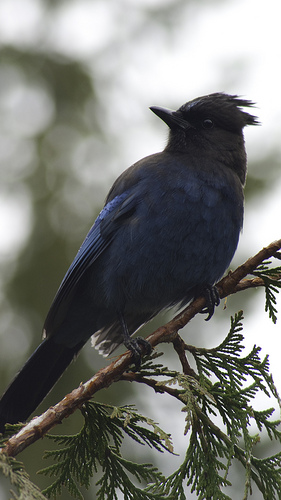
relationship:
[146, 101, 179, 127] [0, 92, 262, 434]
beak of bird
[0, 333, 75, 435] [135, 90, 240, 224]
tail of bird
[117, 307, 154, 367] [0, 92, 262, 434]
leg of bird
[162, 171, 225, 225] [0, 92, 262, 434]
feathers of bird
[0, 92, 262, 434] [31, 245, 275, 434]
bird on limb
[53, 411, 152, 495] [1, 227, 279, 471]
leaves on tree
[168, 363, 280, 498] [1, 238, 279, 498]
leaves on tree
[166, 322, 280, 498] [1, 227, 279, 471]
leaves on tree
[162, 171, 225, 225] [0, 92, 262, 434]
feathers on bird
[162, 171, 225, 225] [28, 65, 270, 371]
feathers on bird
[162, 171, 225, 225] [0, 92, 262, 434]
feathers part of bird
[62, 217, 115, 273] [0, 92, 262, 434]
bird's wing part of bird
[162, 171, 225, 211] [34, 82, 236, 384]
feathers part of bird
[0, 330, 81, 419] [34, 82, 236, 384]
tail part of bird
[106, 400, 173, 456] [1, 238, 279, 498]
needles part of tree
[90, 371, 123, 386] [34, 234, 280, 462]
bark part of branch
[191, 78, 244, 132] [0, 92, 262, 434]
spiky feathers part of bird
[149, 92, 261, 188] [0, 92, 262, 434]
head part of bird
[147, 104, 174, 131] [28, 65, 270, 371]
beak part of bird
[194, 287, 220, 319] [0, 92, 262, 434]
claw part of bird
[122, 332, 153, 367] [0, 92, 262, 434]
claw part of bird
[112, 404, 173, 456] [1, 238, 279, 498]
needles part of tree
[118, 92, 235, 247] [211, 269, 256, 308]
bird perched on branch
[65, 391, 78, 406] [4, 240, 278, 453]
bark part of branch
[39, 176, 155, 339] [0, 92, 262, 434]
bird's wing part of bird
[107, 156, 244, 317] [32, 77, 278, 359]
body of bird